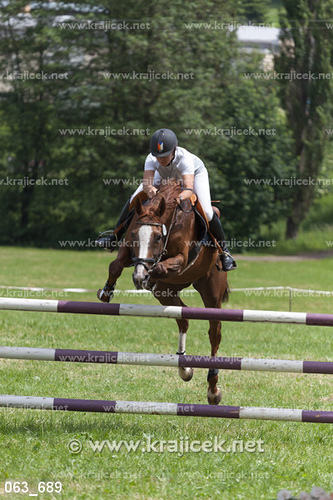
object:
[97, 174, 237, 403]
horse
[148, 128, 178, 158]
helmet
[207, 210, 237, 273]
boots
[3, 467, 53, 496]
numbers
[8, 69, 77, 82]
text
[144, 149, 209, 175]
shirt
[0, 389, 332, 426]
poles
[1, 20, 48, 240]
trees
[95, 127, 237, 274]
woman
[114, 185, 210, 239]
saddle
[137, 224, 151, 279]
white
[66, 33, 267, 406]
front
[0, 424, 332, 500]
grass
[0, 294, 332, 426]
hurdle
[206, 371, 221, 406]
hooves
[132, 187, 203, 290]
reigns